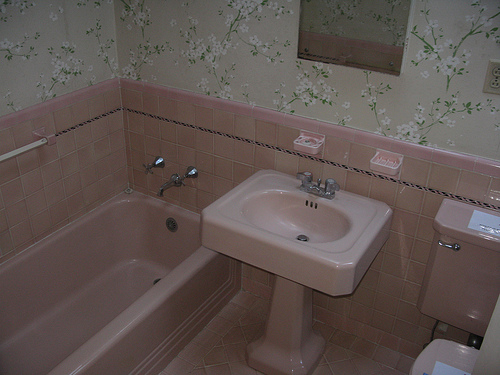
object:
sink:
[202, 168, 392, 375]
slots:
[305, 199, 318, 209]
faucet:
[296, 170, 340, 200]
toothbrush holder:
[369, 147, 404, 180]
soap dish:
[293, 129, 325, 154]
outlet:
[438, 322, 449, 331]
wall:
[119, 0, 498, 374]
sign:
[468, 209, 500, 239]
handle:
[438, 240, 461, 251]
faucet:
[142, 157, 199, 197]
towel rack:
[0, 127, 57, 165]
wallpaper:
[0, 0, 499, 177]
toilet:
[408, 193, 500, 374]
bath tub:
[0, 191, 240, 374]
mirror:
[296, 0, 415, 77]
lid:
[409, 338, 485, 374]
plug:
[125, 188, 133, 194]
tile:
[0, 78, 499, 374]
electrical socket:
[482, 60, 499, 94]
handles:
[296, 170, 340, 199]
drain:
[297, 234, 308, 242]